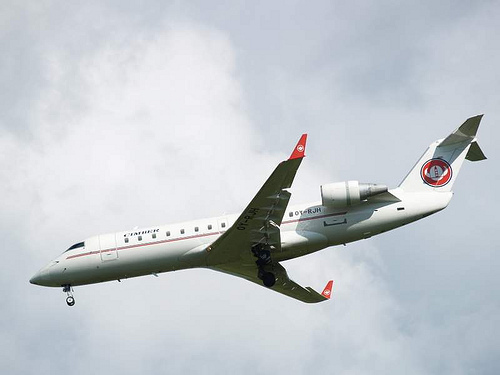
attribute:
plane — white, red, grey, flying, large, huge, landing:
[64, 114, 474, 311]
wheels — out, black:
[250, 246, 288, 295]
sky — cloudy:
[205, 17, 353, 77]